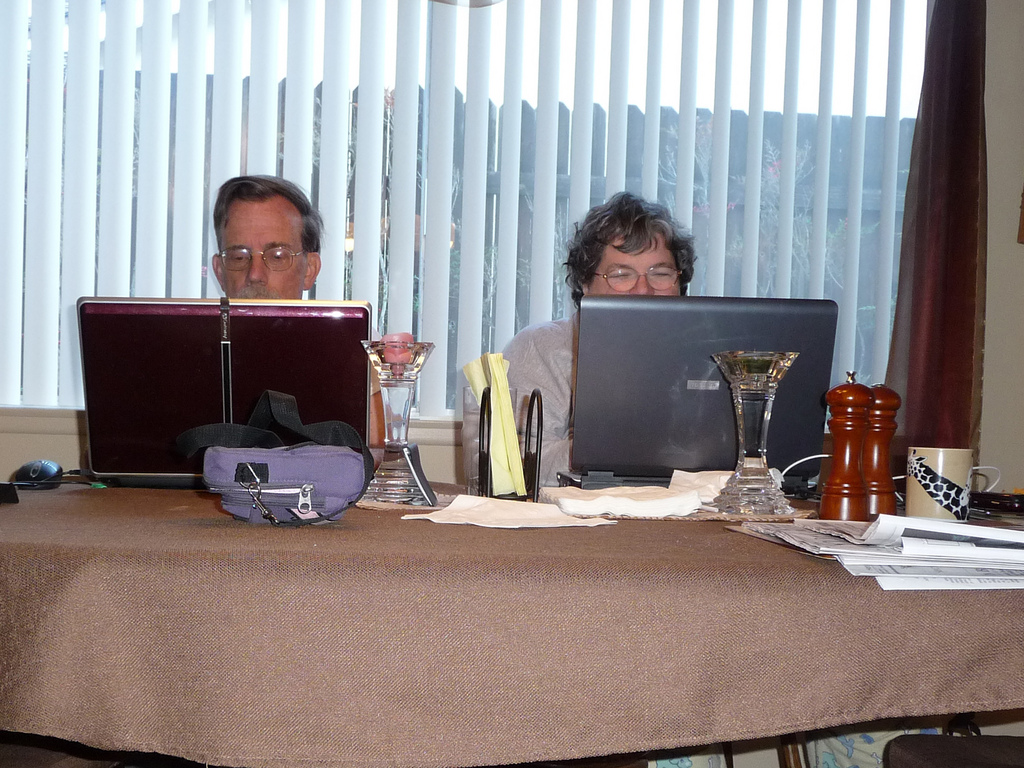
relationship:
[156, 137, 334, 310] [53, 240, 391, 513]
person looking at computer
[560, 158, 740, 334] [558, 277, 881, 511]
person looking at computer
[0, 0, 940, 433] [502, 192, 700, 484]
blinds partially open behind person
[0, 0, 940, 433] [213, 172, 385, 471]
blinds partially open behind man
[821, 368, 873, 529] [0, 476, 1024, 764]
shaker on table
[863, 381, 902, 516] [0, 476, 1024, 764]
shaker on table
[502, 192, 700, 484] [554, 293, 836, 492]
person working on computer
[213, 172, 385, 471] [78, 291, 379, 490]
man working on computer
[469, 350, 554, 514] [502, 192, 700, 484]
holder between person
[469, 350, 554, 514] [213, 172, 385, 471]
holder between man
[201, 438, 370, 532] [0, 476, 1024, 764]
pouch on table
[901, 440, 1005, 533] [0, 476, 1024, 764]
mug on table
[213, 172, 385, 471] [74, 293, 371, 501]
man sitting behind laptop computer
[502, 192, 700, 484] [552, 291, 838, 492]
person sitting behind laptop computer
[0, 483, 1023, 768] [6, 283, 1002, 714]
table under computers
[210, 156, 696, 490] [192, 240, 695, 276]
man woman wearing glasses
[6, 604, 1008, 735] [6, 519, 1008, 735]
cloth covering table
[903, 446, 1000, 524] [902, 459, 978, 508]
mug with design giraffe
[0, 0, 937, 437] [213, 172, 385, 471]
blinds behind man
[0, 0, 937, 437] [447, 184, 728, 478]
blinds behind person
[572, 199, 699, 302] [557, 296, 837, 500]
person sitting in front of computer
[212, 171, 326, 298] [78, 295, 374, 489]
man sitting in front of computer